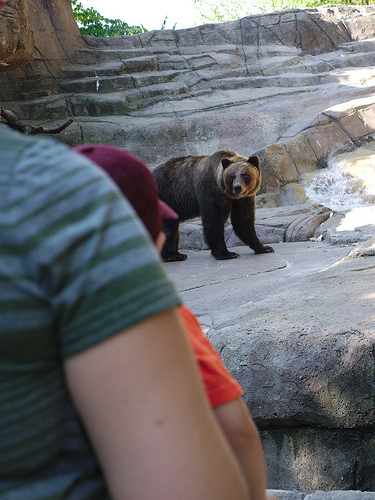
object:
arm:
[50, 177, 253, 500]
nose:
[233, 177, 244, 196]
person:
[71, 143, 266, 500]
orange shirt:
[163, 296, 244, 411]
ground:
[242, 257, 375, 390]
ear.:
[247, 155, 260, 167]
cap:
[70, 143, 179, 245]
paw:
[255, 245, 275, 254]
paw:
[216, 252, 240, 261]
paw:
[161, 254, 188, 262]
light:
[334, 202, 375, 232]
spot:
[67, 144, 268, 500]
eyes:
[230, 175, 235, 179]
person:
[0, 118, 249, 500]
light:
[127, 0, 156, 22]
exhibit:
[0, 0, 375, 122]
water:
[304, 148, 374, 212]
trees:
[70, 1, 375, 39]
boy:
[71, 142, 266, 499]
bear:
[147, 146, 275, 263]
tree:
[71, 1, 180, 39]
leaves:
[70, 0, 151, 38]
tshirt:
[0, 124, 187, 500]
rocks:
[264, 96, 348, 151]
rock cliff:
[268, 332, 374, 487]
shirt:
[0, 125, 184, 500]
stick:
[60, 37, 375, 116]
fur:
[149, 150, 222, 223]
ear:
[221, 155, 232, 171]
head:
[67, 144, 179, 260]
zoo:
[0, 0, 375, 500]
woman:
[0, 119, 254, 500]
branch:
[25, 118, 76, 137]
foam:
[304, 160, 375, 212]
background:
[0, 3, 375, 124]